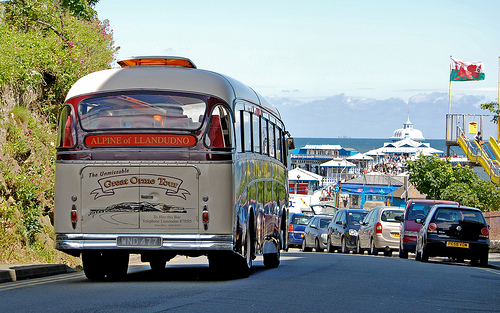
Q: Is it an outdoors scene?
A: Yes, it is outdoors.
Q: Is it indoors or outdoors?
A: It is outdoors.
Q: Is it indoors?
A: No, it is outdoors.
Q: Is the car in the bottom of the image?
A: Yes, the car is in the bottom of the image.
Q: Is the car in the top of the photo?
A: No, the car is in the bottom of the image.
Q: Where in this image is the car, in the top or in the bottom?
A: The car is in the bottom of the image.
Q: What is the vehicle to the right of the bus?
A: The vehicle is a car.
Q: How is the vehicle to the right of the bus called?
A: The vehicle is a car.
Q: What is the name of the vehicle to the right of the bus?
A: The vehicle is a car.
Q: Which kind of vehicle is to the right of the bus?
A: The vehicle is a car.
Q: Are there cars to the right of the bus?
A: Yes, there is a car to the right of the bus.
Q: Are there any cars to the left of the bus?
A: No, the car is to the right of the bus.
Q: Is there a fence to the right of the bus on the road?
A: No, there is a car to the right of the bus.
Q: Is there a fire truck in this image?
A: No, there are no fire trucks.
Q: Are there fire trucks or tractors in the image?
A: No, there are no fire trucks or tractors.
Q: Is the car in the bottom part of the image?
A: Yes, the car is in the bottom of the image.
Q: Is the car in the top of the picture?
A: No, the car is in the bottom of the image.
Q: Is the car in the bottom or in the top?
A: The car is in the bottom of the image.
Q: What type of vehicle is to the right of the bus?
A: The vehicle is a car.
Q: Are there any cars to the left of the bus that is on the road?
A: No, the car is to the right of the bus.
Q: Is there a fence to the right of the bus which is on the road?
A: No, there is a car to the right of the bus.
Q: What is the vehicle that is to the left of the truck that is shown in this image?
A: The vehicle is a car.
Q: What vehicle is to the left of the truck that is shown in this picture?
A: The vehicle is a car.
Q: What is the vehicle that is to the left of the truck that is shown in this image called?
A: The vehicle is a car.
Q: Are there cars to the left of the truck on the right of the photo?
A: Yes, there is a car to the left of the truck.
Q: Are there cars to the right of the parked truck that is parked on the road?
A: No, the car is to the left of the truck.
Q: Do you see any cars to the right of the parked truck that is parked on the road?
A: No, the car is to the left of the truck.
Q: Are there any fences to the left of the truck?
A: No, there is a car to the left of the truck.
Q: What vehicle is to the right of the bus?
A: The vehicle is a car.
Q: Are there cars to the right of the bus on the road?
A: Yes, there is a car to the right of the bus.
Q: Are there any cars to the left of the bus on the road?
A: No, the car is to the right of the bus.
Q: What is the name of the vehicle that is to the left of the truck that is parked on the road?
A: The vehicle is a car.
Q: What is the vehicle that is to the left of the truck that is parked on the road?
A: The vehicle is a car.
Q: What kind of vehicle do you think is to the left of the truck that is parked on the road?
A: The vehicle is a car.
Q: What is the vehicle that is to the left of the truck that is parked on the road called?
A: The vehicle is a car.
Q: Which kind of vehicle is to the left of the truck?
A: The vehicle is a car.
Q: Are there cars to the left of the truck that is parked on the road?
A: Yes, there is a car to the left of the truck.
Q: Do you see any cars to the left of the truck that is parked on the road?
A: Yes, there is a car to the left of the truck.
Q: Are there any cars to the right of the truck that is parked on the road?
A: No, the car is to the left of the truck.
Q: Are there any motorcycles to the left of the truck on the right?
A: No, there is a car to the left of the truck.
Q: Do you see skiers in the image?
A: No, there are no skiers.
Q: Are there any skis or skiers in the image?
A: No, there are no skiers or skis.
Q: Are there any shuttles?
A: No, there are no shuttles.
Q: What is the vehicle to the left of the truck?
A: The vehicle is a car.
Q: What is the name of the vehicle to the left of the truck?
A: The vehicle is a car.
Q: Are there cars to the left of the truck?
A: Yes, there is a car to the left of the truck.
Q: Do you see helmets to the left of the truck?
A: No, there is a car to the left of the truck.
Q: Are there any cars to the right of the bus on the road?
A: Yes, there is a car to the right of the bus.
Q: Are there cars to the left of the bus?
A: No, the car is to the right of the bus.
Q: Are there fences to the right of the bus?
A: No, there is a car to the right of the bus.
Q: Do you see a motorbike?
A: No, there are no motorcycles.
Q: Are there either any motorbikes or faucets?
A: No, there are no motorbikes or faucets.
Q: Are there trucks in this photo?
A: Yes, there is a truck.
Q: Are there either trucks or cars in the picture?
A: Yes, there is a truck.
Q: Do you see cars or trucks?
A: Yes, there is a truck.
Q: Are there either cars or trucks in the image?
A: Yes, there is a truck.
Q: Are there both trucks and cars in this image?
A: Yes, there are both a truck and a car.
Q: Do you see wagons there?
A: No, there are no wagons.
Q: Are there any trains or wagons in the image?
A: No, there are no wagons or trains.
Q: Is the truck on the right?
A: Yes, the truck is on the right of the image.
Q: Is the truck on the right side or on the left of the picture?
A: The truck is on the right of the image.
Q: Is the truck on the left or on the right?
A: The truck is on the right of the image.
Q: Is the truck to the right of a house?
A: No, the truck is to the right of a car.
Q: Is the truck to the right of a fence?
A: No, the truck is to the right of the car.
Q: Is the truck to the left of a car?
A: No, the truck is to the right of a car.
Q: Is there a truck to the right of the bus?
A: Yes, there is a truck to the right of the bus.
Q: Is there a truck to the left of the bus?
A: No, the truck is to the right of the bus.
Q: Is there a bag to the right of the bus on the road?
A: No, there is a truck to the right of the bus.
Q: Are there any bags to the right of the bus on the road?
A: No, there is a truck to the right of the bus.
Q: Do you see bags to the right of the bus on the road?
A: No, there is a truck to the right of the bus.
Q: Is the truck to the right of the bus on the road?
A: Yes, the truck is to the right of the bus.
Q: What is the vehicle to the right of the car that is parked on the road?
A: The vehicle is a truck.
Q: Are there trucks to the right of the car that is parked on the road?
A: Yes, there is a truck to the right of the car.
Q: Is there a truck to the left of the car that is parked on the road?
A: No, the truck is to the right of the car.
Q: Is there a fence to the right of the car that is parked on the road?
A: No, there is a truck to the right of the car.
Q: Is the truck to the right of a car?
A: Yes, the truck is to the right of a car.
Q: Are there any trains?
A: No, there are no trains.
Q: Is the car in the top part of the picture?
A: No, the car is in the bottom of the image.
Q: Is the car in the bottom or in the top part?
A: The car is in the bottom of the image.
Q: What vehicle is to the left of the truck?
A: The vehicle is a car.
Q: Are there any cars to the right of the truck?
A: No, the car is to the left of the truck.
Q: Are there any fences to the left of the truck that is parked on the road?
A: No, there is a car to the left of the truck.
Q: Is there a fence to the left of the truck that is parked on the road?
A: No, there is a car to the left of the truck.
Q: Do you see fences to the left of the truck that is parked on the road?
A: No, there is a car to the left of the truck.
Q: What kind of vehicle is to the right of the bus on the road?
A: The vehicle is a car.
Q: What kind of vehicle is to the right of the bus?
A: The vehicle is a car.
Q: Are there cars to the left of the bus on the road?
A: No, the car is to the right of the bus.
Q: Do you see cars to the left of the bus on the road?
A: No, the car is to the right of the bus.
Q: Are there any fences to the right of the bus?
A: No, there is a car to the right of the bus.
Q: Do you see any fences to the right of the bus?
A: No, there is a car to the right of the bus.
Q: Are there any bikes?
A: No, there are no bikes.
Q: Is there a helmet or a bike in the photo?
A: No, there are no bikes or helmets.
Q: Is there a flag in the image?
A: Yes, there is a flag.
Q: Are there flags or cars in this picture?
A: Yes, there is a flag.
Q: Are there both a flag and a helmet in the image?
A: No, there is a flag but no helmets.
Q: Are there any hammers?
A: No, there are no hammers.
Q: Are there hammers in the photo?
A: No, there are no hammers.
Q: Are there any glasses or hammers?
A: No, there are no hammers or glasses.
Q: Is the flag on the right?
A: Yes, the flag is on the right of the image.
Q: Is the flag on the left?
A: No, the flag is on the right of the image.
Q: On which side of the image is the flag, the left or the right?
A: The flag is on the right of the image.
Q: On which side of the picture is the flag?
A: The flag is on the right of the image.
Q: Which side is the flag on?
A: The flag is on the right of the image.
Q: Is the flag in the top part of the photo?
A: Yes, the flag is in the top of the image.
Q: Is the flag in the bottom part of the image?
A: No, the flag is in the top of the image.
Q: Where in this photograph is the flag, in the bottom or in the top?
A: The flag is in the top of the image.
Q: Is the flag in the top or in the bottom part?
A: The flag is in the top of the image.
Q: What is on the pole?
A: The flag is on the pole.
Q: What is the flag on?
A: The flag is on the pole.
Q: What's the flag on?
A: The flag is on the pole.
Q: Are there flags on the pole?
A: Yes, there is a flag on the pole.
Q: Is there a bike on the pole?
A: No, there is a flag on the pole.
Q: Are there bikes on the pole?
A: No, there is a flag on the pole.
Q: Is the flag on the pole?
A: Yes, the flag is on the pole.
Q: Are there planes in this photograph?
A: No, there are no planes.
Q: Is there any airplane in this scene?
A: No, there are no airplanes.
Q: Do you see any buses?
A: Yes, there is a bus.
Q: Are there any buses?
A: Yes, there is a bus.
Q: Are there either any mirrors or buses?
A: Yes, there is a bus.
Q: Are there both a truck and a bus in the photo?
A: Yes, there are both a bus and a truck.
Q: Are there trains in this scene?
A: No, there are no trains.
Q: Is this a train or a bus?
A: This is a bus.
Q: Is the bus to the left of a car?
A: Yes, the bus is to the left of a car.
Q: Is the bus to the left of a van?
A: No, the bus is to the left of a car.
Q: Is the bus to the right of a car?
A: No, the bus is to the left of a car.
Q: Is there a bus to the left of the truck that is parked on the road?
A: Yes, there is a bus to the left of the truck.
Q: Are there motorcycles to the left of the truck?
A: No, there is a bus to the left of the truck.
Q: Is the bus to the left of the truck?
A: Yes, the bus is to the left of the truck.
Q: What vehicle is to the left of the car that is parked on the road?
A: The vehicle is a bus.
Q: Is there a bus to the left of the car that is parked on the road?
A: Yes, there is a bus to the left of the car.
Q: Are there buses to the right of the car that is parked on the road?
A: No, the bus is to the left of the car.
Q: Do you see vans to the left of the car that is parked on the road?
A: No, there is a bus to the left of the car.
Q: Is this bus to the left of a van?
A: No, the bus is to the left of the car.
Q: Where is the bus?
A: The bus is on the road.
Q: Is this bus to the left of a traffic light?
A: No, the bus is to the left of a car.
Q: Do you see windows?
A: Yes, there is a window.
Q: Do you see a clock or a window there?
A: Yes, there is a window.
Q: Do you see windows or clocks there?
A: Yes, there is a window.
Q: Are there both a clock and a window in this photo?
A: No, there is a window but no clocks.